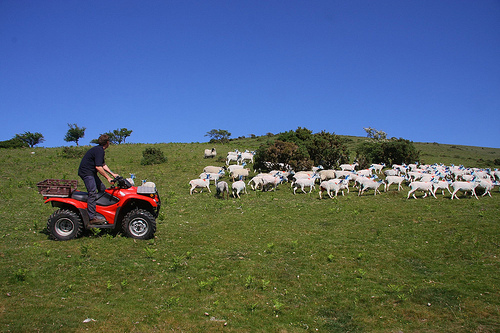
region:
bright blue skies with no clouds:
[47, 10, 487, 97]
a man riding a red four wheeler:
[47, 136, 155, 235]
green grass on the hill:
[181, 230, 477, 314]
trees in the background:
[9, 117, 86, 155]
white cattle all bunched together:
[197, 169, 494, 206]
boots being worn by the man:
[88, 216, 110, 227]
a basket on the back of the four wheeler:
[38, 175, 75, 199]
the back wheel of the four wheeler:
[45, 208, 81, 238]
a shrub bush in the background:
[136, 143, 177, 172]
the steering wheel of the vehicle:
[110, 172, 132, 186]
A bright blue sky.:
[0, 0, 497, 150]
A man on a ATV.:
[76, 132, 121, 225]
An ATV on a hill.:
[36, 173, 161, 241]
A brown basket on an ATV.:
[35, 176, 80, 197]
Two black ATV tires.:
[43, 206, 157, 242]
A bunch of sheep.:
[186, 146, 499, 201]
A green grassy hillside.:
[4, 132, 498, 332]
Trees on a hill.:
[0, 121, 135, 149]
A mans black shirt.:
[76, 142, 106, 177]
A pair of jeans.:
[78, 171, 107, 219]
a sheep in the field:
[186, 174, 214, 194]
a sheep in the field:
[228, 174, 245, 194]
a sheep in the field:
[203, 162, 225, 171]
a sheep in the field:
[292, 174, 319, 194]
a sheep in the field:
[353, 168, 385, 195]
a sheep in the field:
[407, 178, 437, 200]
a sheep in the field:
[446, 177, 476, 199]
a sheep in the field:
[198, 143, 216, 154]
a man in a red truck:
[29, 120, 160, 251]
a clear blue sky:
[1, 0, 498, 156]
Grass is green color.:
[240, 221, 368, 288]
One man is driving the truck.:
[36, 140, 166, 245]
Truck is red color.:
[36, 175, 156, 235]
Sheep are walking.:
[196, 142, 473, 209]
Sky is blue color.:
[70, 45, 355, 95]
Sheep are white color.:
[197, 165, 479, 201]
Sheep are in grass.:
[196, 160, 486, 215]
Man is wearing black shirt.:
[75, 145, 106, 172]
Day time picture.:
[15, 70, 480, 312]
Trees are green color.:
[8, 125, 88, 145]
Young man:
[55, 120, 122, 185]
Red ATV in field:
[40, 175, 183, 240]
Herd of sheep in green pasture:
[188, 152, 494, 212]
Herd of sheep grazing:
[190, 122, 488, 237]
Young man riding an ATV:
[36, 135, 166, 251]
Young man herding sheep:
[21, 105, 478, 246]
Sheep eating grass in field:
[177, 135, 497, 217]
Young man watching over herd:
[45, 116, 468, 248]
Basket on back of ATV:
[38, 165, 84, 218]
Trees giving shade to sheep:
[196, 131, 463, 193]